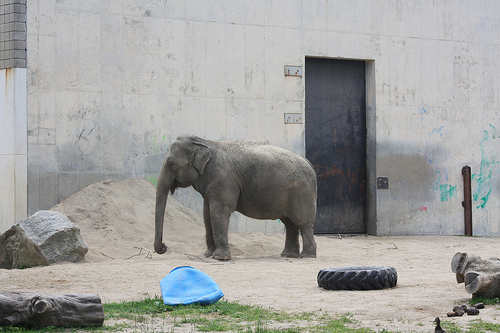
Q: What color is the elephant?
A: Grey.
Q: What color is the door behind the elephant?
A: Black.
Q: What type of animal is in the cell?
A: Grey elephant.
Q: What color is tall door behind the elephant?
A: Black.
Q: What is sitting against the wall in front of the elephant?
A: Sand.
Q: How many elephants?
A: 1.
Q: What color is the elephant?
A: Gray.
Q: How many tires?
A: 1.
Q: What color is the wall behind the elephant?
A: Gray.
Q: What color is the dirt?
A: Brown.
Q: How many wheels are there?
A: One.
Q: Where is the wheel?
A: On the ground.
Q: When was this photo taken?
A: Daytime.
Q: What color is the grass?
A: Green.